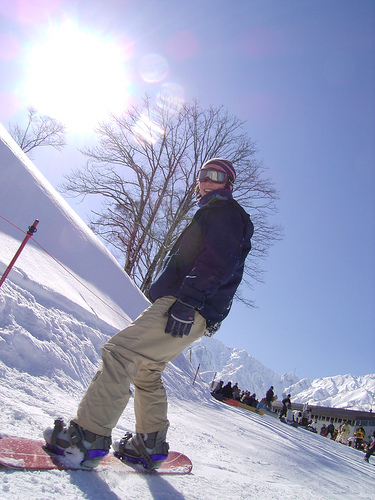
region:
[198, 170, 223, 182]
snow goggles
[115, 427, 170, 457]
grey snow boot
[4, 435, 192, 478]
a red snow board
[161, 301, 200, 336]
dark blue gloves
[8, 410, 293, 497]
snow covers the ground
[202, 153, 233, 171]
a dark blue and red beanie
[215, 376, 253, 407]
people in the background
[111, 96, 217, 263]
trees with no leaves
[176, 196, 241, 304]
a dark blue jacket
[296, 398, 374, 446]
a building in the background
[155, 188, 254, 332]
the jacket is blue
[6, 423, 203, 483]
the snowboard is red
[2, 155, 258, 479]
person on ski board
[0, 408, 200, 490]
ski board is red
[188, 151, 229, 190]
person wearing reflective goggles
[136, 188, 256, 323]
person wearing blue jacket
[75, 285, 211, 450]
person wearing khaki pants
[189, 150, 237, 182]
person wearing multicolored hat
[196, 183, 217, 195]
person has open mouth smile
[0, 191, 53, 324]
red stake in ground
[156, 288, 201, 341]
person wearing blue gloves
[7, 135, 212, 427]
snow pushed in pile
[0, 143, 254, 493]
Individual on a snowboard smiling.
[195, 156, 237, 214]
Snowboarder wearing a hat and goggles.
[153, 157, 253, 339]
Snowboarder wearing a jacket and gloves.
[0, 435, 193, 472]
Red snow board.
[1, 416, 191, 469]
Snowboarding boots on a red snowboard.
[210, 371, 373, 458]
Dozens of people enjoying the snow.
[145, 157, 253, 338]
Snowboarder smiling in a hat and goggles.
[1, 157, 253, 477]
Individual smiling while riding a snowboard.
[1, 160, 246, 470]
Individual smiling while snowboarding on a sunny day.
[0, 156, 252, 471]
Individual wearing snowboarding gear.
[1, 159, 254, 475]
a snowboarder going downhill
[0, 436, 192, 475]
a red snowboard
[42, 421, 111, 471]
a grey and blue snow boot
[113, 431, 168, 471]
a grey and blue snow boot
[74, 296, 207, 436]
a pair of tan snow pants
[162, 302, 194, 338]
a blue snow glove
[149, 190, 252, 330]
a blue winter coat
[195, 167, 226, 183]
a pair of protective eyewear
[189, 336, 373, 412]
snowy mountains in distance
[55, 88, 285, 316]
large bare tree in distance